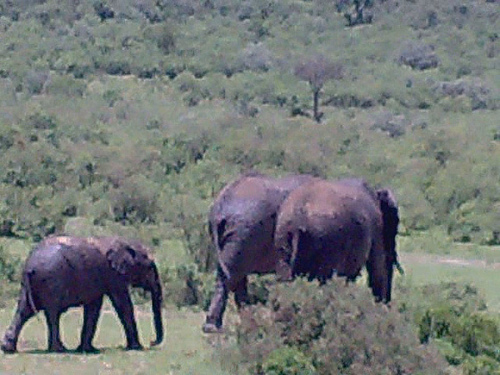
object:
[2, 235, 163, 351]
baby elephant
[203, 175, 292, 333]
big elephant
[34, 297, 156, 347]
legs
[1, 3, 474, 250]
trees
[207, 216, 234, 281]
tail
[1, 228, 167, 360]
baby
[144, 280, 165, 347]
trunk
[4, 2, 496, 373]
grass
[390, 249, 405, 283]
tusk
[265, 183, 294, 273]
side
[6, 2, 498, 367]
ground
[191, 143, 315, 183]
wall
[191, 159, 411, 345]
elephant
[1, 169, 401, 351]
elephants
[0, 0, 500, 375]
bushes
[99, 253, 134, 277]
ear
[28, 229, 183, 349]
elephant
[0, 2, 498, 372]
field